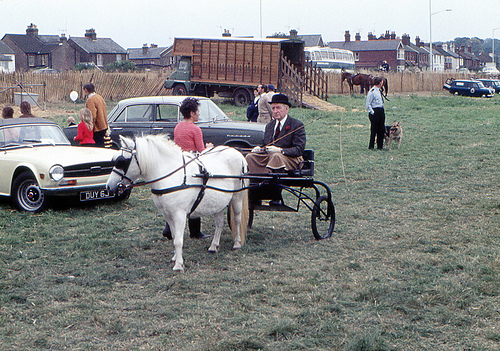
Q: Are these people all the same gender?
A: No, they are both male and female.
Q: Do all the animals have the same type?
A: No, there are both horses and dogs.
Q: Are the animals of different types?
A: Yes, they are horses and dogs.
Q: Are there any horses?
A: Yes, there is a horse.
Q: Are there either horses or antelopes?
A: Yes, there is a horse.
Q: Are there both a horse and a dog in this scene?
A: Yes, there are both a horse and a dog.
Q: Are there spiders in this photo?
A: No, there are no spiders.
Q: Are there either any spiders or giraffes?
A: No, there are no spiders or giraffes.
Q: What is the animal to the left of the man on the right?
A: The animal is a horse.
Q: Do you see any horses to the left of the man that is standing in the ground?
A: Yes, there is a horse to the left of the man.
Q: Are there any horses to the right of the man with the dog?
A: No, the horse is to the left of the man.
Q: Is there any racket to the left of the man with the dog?
A: No, there is a horse to the left of the man.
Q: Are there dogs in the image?
A: Yes, there is a dog.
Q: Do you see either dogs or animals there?
A: Yes, there is a dog.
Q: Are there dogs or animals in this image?
A: Yes, there is a dog.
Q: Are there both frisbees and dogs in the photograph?
A: No, there is a dog but no frisbees.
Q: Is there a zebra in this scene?
A: No, there are no zebras.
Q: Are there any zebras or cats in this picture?
A: No, there are no zebras or cats.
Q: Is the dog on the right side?
A: Yes, the dog is on the right of the image.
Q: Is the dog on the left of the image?
A: No, the dog is on the right of the image.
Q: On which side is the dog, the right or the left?
A: The dog is on the right of the image.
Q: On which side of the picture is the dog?
A: The dog is on the right of the image.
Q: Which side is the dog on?
A: The dog is on the right of the image.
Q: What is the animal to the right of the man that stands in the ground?
A: The animal is a dog.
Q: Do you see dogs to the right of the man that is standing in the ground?
A: Yes, there is a dog to the right of the man.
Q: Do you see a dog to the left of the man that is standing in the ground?
A: No, the dog is to the right of the man.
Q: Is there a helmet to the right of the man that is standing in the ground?
A: No, there is a dog to the right of the man.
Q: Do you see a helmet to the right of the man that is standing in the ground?
A: No, there is a dog to the right of the man.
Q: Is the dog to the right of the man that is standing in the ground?
A: Yes, the dog is to the right of the man.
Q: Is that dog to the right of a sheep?
A: No, the dog is to the right of the man.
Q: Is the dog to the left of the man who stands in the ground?
A: No, the dog is to the right of the man.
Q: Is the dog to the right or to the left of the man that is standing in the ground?
A: The dog is to the right of the man.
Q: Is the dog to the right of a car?
A: Yes, the dog is to the right of a car.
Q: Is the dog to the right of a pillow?
A: No, the dog is to the right of a car.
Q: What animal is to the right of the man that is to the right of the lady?
A: The animal is a dog.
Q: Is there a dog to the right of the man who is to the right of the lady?
A: Yes, there is a dog to the right of the man.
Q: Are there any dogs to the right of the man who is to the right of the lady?
A: Yes, there is a dog to the right of the man.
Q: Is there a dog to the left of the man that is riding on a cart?
A: No, the dog is to the right of the man.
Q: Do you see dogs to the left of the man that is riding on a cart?
A: No, the dog is to the right of the man.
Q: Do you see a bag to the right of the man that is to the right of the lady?
A: No, there is a dog to the right of the man.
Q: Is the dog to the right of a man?
A: Yes, the dog is to the right of a man.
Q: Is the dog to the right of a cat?
A: No, the dog is to the right of a man.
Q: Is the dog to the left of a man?
A: No, the dog is to the right of a man.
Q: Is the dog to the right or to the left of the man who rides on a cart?
A: The dog is to the right of the man.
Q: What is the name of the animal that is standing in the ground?
A: The animal is a dog.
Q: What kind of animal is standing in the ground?
A: The animal is a dog.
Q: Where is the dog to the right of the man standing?
A: The dog is standing in the ground.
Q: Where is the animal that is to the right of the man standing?
A: The dog is standing in the ground.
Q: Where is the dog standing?
A: The dog is standing in the ground.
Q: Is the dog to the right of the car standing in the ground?
A: Yes, the dog is standing in the ground.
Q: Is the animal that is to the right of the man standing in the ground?
A: Yes, the dog is standing in the ground.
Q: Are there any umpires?
A: No, there are no umpires.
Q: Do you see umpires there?
A: No, there are no umpires.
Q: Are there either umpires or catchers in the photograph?
A: No, there are no umpires or catchers.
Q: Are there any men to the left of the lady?
A: Yes, there is a man to the left of the lady.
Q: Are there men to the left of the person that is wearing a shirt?
A: Yes, there is a man to the left of the lady.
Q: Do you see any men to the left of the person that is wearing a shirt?
A: Yes, there is a man to the left of the lady.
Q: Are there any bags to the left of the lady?
A: No, there is a man to the left of the lady.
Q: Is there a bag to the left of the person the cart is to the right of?
A: No, there is a man to the left of the lady.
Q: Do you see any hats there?
A: Yes, there is a hat.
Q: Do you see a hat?
A: Yes, there is a hat.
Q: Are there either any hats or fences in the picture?
A: Yes, there is a hat.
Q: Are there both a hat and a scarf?
A: No, there is a hat but no scarves.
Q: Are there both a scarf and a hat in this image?
A: No, there is a hat but no scarves.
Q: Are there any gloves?
A: No, there are no gloves.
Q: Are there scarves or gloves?
A: No, there are no gloves or scarves.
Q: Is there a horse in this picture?
A: Yes, there is a horse.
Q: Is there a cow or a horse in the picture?
A: Yes, there is a horse.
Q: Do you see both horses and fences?
A: Yes, there are both a horse and a fence.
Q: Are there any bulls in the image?
A: No, there are no bulls.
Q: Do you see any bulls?
A: No, there are no bulls.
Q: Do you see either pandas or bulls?
A: No, there are no bulls or pandas.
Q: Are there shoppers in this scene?
A: No, there are no shoppers.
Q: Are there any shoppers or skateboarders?
A: No, there are no shoppers or skateboarders.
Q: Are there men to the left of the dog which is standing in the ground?
A: Yes, there is a man to the left of the dog.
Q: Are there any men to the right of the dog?
A: No, the man is to the left of the dog.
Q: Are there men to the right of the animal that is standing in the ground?
A: No, the man is to the left of the dog.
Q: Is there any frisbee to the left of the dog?
A: No, there is a man to the left of the dog.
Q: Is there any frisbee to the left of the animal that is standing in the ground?
A: No, there is a man to the left of the dog.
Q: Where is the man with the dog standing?
A: The man is standing in the ground.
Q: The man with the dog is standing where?
A: The man is standing in the ground.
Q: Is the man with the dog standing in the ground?
A: Yes, the man is standing in the ground.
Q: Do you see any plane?
A: No, there are no airplanes.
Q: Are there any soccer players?
A: No, there are no soccer players.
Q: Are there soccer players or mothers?
A: No, there are no soccer players or mothers.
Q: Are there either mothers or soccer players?
A: No, there are no soccer players or mothers.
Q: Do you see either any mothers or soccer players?
A: No, there are no soccer players or mothers.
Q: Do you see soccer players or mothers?
A: No, there are no soccer players or mothers.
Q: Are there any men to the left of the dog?
A: Yes, there is a man to the left of the dog.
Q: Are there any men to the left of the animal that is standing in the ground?
A: Yes, there is a man to the left of the dog.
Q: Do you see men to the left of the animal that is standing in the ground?
A: Yes, there is a man to the left of the dog.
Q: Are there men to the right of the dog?
A: No, the man is to the left of the dog.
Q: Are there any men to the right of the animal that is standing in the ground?
A: No, the man is to the left of the dog.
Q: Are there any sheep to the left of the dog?
A: No, there is a man to the left of the dog.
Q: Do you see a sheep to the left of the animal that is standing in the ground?
A: No, there is a man to the left of the dog.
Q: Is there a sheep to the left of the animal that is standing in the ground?
A: No, there is a man to the left of the dog.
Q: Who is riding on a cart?
A: The man is riding on a cart.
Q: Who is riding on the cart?
A: The man is riding on a cart.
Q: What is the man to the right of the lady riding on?
A: The man is riding on a cart.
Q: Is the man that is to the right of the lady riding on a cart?
A: Yes, the man is riding on a cart.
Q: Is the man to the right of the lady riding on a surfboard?
A: No, the man is riding on a cart.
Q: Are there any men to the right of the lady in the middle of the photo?
A: Yes, there is a man to the right of the lady.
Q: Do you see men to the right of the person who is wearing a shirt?
A: Yes, there is a man to the right of the lady.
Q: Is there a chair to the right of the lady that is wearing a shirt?
A: No, there is a man to the right of the lady.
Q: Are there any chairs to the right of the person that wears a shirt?
A: No, there is a man to the right of the lady.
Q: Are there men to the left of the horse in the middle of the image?
A: No, the man is to the right of the horse.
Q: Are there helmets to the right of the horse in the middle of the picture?
A: No, there is a man to the right of the horse.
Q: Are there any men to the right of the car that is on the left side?
A: Yes, there is a man to the right of the car.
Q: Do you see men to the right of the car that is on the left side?
A: Yes, there is a man to the right of the car.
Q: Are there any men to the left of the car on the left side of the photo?
A: No, the man is to the right of the car.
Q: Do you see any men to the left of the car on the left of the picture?
A: No, the man is to the right of the car.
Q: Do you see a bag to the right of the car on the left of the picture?
A: No, there is a man to the right of the car.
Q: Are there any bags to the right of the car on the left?
A: No, there is a man to the right of the car.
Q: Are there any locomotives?
A: No, there are no locomotives.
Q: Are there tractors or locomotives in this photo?
A: No, there are no locomotives or tractors.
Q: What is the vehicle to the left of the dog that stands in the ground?
A: The vehicle is a car.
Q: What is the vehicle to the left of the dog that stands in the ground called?
A: The vehicle is a car.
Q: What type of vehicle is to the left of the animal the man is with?
A: The vehicle is a car.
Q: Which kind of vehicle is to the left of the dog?
A: The vehicle is a car.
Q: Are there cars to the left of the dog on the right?
A: Yes, there is a car to the left of the dog.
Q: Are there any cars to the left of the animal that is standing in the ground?
A: Yes, there is a car to the left of the dog.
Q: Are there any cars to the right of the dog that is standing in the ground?
A: No, the car is to the left of the dog.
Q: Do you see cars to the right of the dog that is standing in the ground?
A: No, the car is to the left of the dog.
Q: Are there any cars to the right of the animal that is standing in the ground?
A: No, the car is to the left of the dog.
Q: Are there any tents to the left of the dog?
A: No, there is a car to the left of the dog.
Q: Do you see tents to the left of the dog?
A: No, there is a car to the left of the dog.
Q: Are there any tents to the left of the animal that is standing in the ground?
A: No, there is a car to the left of the dog.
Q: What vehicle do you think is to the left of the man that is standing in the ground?
A: The vehicle is a car.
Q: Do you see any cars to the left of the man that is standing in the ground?
A: Yes, there is a car to the left of the man.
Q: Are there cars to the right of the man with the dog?
A: No, the car is to the left of the man.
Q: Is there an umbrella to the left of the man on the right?
A: No, there is a car to the left of the man.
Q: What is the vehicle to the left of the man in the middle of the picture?
A: The vehicle is a car.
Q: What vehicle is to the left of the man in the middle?
A: The vehicle is a car.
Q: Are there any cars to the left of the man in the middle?
A: Yes, there is a car to the left of the man.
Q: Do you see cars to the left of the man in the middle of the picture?
A: Yes, there is a car to the left of the man.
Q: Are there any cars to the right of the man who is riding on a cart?
A: No, the car is to the left of the man.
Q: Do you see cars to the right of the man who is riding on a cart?
A: No, the car is to the left of the man.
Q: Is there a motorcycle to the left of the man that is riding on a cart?
A: No, there is a car to the left of the man.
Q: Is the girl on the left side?
A: Yes, the girl is on the left of the image.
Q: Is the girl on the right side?
A: No, the girl is on the left of the image.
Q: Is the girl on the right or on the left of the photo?
A: The girl is on the left of the image.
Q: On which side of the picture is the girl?
A: The girl is on the left of the image.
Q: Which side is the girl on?
A: The girl is on the left of the image.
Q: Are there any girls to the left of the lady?
A: Yes, there is a girl to the left of the lady.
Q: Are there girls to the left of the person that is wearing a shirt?
A: Yes, there is a girl to the left of the lady.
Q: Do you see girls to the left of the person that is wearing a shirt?
A: Yes, there is a girl to the left of the lady.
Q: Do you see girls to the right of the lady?
A: No, the girl is to the left of the lady.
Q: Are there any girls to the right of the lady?
A: No, the girl is to the left of the lady.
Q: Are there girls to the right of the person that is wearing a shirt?
A: No, the girl is to the left of the lady.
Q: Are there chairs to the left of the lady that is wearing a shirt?
A: No, there is a girl to the left of the lady.